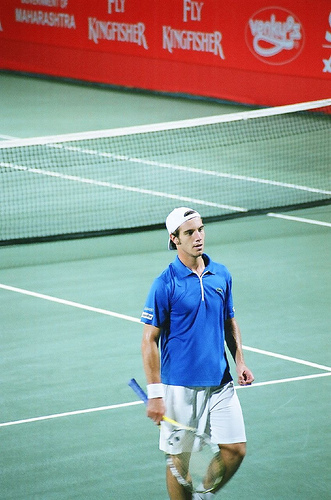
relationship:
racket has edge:
[120, 367, 228, 495] [164, 455, 191, 490]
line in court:
[2, 276, 331, 380] [1, 69, 328, 498]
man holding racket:
[141, 204, 258, 500] [120, 367, 228, 495]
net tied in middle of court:
[1, 91, 328, 254] [1, 69, 328, 498]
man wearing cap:
[141, 204, 258, 500] [164, 203, 201, 254]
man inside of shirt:
[141, 204, 258, 500] [138, 252, 238, 394]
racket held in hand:
[120, 367, 228, 495] [141, 398, 170, 425]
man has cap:
[141, 204, 258, 500] [164, 203, 201, 254]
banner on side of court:
[2, 0, 330, 118] [1, 69, 328, 498]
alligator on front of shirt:
[214, 284, 226, 298] [138, 252, 238, 394]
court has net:
[1, 69, 328, 498] [1, 91, 328, 254]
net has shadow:
[1, 91, 328, 254] [2, 224, 330, 271]